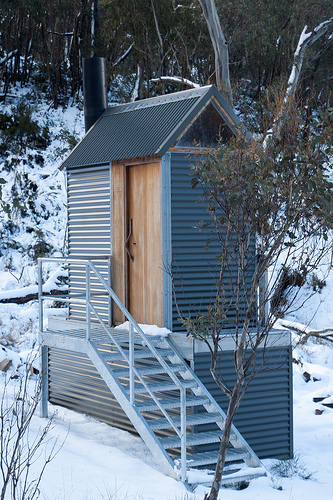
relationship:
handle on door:
[125, 219, 134, 265] [126, 163, 166, 323]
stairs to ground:
[84, 332, 275, 491] [3, 369, 332, 500]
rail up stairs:
[36, 254, 187, 467] [84, 332, 275, 491]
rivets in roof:
[108, 86, 206, 113] [55, 86, 214, 171]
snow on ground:
[51, 410, 172, 500] [3, 369, 332, 500]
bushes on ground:
[1, 332, 63, 500] [3, 369, 332, 500]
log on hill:
[1, 277, 69, 304] [1, 76, 80, 415]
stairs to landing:
[84, 332, 275, 491] [44, 319, 163, 344]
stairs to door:
[84, 332, 275, 491] [126, 163, 166, 323]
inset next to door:
[112, 161, 128, 330] [126, 163, 166, 323]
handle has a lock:
[125, 219, 134, 265] [130, 238, 140, 252]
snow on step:
[51, 410, 172, 500] [182, 460, 275, 494]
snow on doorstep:
[51, 410, 172, 500] [112, 319, 173, 336]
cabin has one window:
[42, 85, 295, 444] [173, 100, 248, 151]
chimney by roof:
[82, 52, 108, 131] [55, 86, 214, 171]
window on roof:
[173, 100, 248, 151] [56, 84, 255, 172]